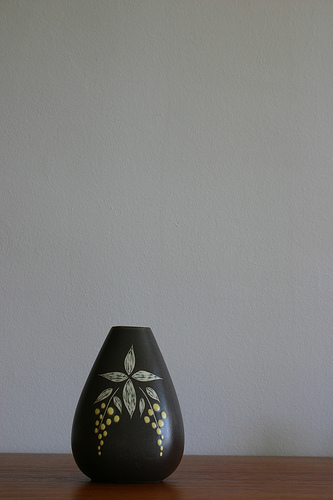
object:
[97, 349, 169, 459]
design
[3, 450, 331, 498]
surface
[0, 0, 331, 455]
wall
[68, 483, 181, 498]
shadow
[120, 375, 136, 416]
leaf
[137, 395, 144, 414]
leaf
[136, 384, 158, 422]
stem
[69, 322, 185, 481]
jar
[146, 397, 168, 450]
colour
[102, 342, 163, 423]
flowers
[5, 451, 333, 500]
furniture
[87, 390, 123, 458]
grapes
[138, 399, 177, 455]
grapes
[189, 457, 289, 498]
wood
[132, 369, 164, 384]
petal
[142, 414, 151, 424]
dots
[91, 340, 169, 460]
plant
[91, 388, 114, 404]
leaves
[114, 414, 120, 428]
dots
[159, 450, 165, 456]
dots